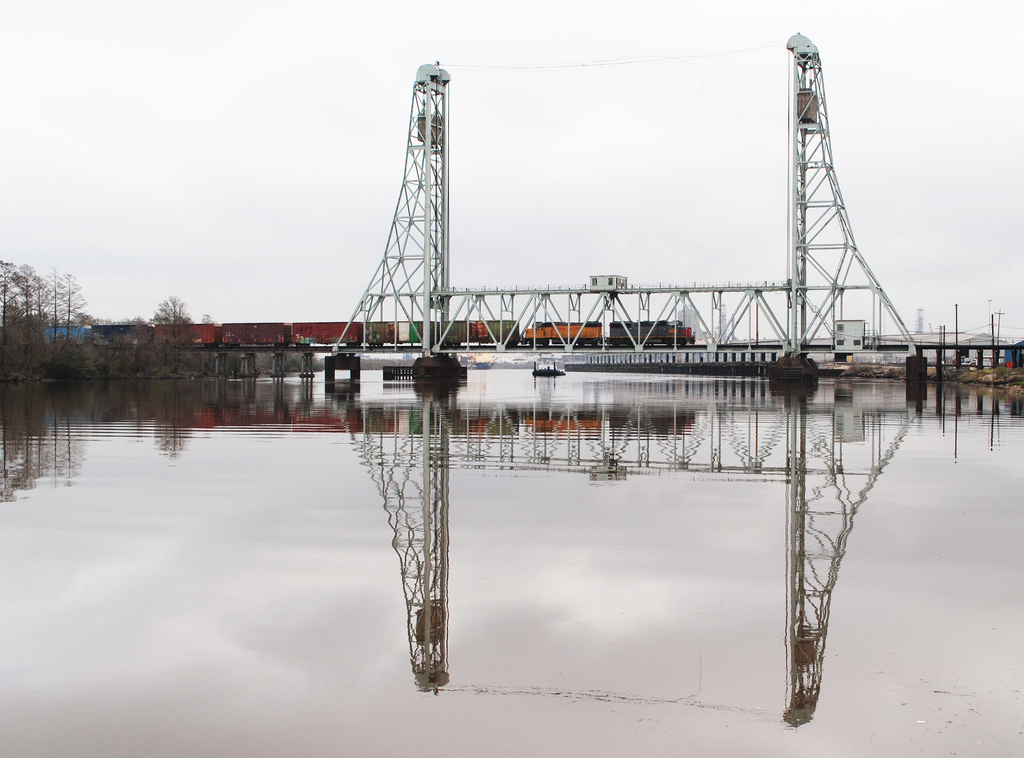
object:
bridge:
[216, 31, 1024, 377]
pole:
[564, 293, 573, 352]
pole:
[529, 293, 538, 351]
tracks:
[0, 343, 1022, 381]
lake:
[0, 369, 1024, 758]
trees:
[0, 259, 202, 377]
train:
[43, 320, 697, 348]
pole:
[465, 292, 471, 351]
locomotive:
[43, 320, 695, 350]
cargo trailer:
[154, 324, 222, 347]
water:
[0, 369, 1024, 758]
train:
[340, 320, 696, 348]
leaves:
[0, 260, 46, 375]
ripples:
[0, 381, 696, 445]